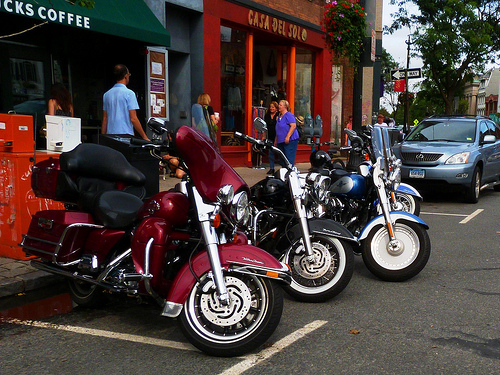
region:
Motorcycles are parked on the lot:
[21, 11, 481, 356]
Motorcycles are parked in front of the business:
[1, 10, 471, 348]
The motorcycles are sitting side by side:
[11, 38, 459, 350]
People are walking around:
[15, 13, 485, 360]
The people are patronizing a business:
[5, 17, 480, 372]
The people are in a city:
[15, 25, 488, 342]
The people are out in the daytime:
[12, 35, 492, 340]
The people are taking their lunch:
[6, 35, 492, 363]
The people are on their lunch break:
[33, 0, 480, 350]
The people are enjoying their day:
[7, 20, 466, 334]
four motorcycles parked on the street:
[18, 122, 432, 356]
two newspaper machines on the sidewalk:
[1, 115, 95, 257]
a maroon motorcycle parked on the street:
[19, 117, 293, 356]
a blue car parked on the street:
[394, 114, 499, 206]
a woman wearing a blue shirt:
[275, 100, 300, 165]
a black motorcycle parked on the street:
[227, 127, 362, 304]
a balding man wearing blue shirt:
[99, 62, 148, 142]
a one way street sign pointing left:
[386, 36, 426, 131]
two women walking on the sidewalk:
[263, 98, 300, 176]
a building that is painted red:
[204, 27, 335, 167]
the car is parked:
[393, 108, 488, 217]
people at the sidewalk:
[73, 60, 358, 171]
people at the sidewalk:
[85, 70, 410, 257]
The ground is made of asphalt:
[331, 315, 474, 360]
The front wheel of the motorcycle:
[180, 248, 289, 354]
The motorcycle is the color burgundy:
[18, 130, 288, 326]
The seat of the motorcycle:
[54, 140, 151, 227]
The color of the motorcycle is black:
[233, 125, 360, 302]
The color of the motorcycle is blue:
[329, 121, 439, 288]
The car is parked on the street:
[402, 108, 499, 205]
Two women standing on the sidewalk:
[259, 90, 309, 177]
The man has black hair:
[103, 58, 138, 83]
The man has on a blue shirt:
[99, 80, 139, 140]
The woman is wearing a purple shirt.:
[268, 98, 306, 183]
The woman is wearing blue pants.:
[271, 92, 302, 177]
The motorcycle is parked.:
[13, 118, 303, 364]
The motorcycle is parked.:
[108, 115, 363, 306]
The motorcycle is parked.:
[252, 123, 439, 285]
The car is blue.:
[388, 103, 498, 206]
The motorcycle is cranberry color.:
[11, 107, 294, 357]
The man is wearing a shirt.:
[96, 55, 159, 153]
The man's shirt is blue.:
[86, 49, 168, 157]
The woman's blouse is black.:
[257, 92, 284, 177]